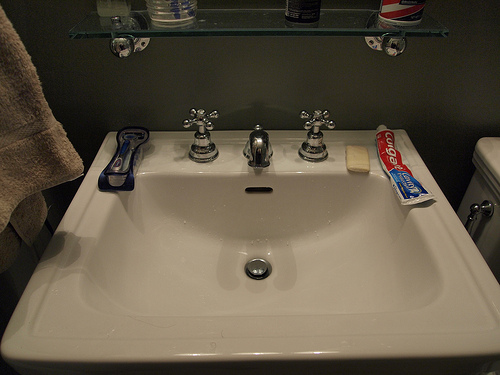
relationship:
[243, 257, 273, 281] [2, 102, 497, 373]
drain in sink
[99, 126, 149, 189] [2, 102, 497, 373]
razor in sink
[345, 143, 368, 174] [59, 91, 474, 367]
soap on sink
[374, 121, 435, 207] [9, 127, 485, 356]
toothpaste on sink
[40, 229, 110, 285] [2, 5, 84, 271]
shadow of towel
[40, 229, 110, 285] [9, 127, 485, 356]
shadow on sink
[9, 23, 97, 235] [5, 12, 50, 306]
towel hanging on wall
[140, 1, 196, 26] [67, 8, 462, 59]
glass on shelf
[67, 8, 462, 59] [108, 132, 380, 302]
shelf above sink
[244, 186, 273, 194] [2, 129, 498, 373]
hole in sink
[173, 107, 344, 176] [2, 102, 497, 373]
faucet of sink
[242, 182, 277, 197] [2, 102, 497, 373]
hole of sink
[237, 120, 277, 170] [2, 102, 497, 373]
fixture of sink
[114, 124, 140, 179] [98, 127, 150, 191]
razor in razor container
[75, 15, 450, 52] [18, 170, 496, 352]
glass shelf above sink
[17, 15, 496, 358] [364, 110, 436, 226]
bathroom with hygiene items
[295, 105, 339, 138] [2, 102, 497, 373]
knob on sink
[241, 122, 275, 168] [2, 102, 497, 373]
fixture on sink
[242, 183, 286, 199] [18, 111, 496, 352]
opening in sink